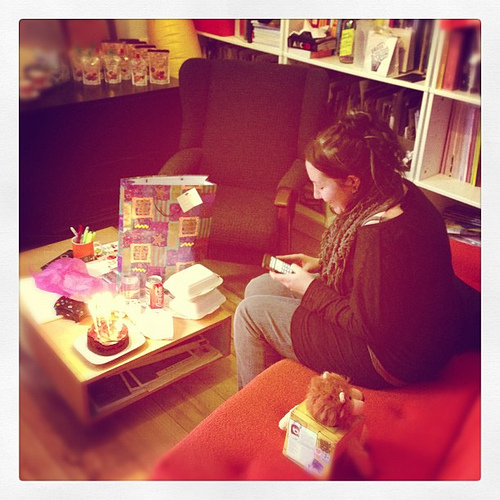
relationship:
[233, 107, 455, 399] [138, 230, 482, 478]
woman on couch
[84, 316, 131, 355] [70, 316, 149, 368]
cake on a plate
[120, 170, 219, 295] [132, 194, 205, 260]
gift bag with multicolor print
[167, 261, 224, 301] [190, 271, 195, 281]
container color white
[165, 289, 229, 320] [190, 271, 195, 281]
container color white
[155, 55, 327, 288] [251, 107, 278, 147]
chair color brown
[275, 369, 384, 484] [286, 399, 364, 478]
lion in box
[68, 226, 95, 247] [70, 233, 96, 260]
pens in cup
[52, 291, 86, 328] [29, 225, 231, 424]
controller for game on table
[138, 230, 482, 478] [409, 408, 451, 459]
sofa color red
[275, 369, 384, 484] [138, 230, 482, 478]
lion sitting on couch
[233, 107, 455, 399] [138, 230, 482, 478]
woman sitting on couch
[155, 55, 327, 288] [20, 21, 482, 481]
chair in same room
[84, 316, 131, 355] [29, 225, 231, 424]
cake sitting on table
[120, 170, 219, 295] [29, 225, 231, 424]
gift bag on table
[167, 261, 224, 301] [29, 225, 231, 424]
container on table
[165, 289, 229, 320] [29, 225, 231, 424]
container on table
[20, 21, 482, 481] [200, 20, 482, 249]
room with a bookshelf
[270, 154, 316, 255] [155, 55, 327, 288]
arm on chair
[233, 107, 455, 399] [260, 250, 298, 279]
woman texting on phone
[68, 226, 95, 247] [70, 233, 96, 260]
pens in mug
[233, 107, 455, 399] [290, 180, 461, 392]
woman wearing a shirt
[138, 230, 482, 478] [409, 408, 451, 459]
couch color red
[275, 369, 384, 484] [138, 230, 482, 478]
lion toy on couch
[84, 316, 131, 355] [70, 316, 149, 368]
cake for birthday on plate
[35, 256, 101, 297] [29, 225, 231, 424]
paper on table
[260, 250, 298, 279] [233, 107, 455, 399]
phone in hands of woman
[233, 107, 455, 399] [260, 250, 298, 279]
woman using phone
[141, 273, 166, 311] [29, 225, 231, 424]
can of soda on table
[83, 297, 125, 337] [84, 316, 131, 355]
candles on top of cake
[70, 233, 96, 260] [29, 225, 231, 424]
cup of pens on table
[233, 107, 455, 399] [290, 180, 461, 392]
woman in a black shirt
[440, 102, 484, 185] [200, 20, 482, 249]
books on bookshelf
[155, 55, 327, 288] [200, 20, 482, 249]
chair by bookshelf